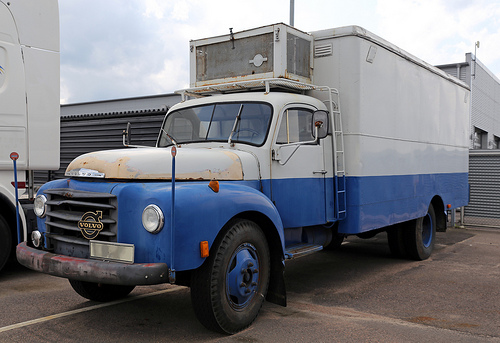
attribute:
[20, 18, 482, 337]
truck — old, blue, white, part, refrigeration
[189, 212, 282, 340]
tire — black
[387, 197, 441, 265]
tire — black, rear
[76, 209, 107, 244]
emblem — logo, round, volvo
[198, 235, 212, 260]
reflector — small, rectangle, orange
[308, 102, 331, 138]
mirror — side, rear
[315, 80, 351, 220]
ladder — rungs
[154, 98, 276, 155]
windows — part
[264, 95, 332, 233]
door — blue, white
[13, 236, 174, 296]
bumper — black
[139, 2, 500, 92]
clouds — white